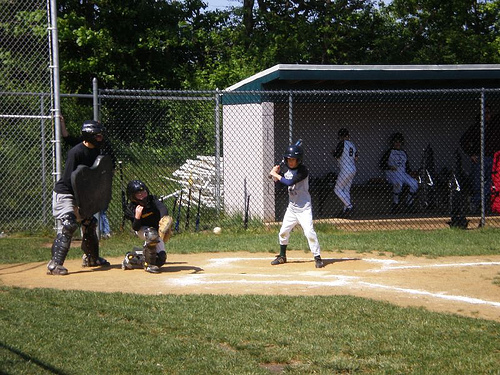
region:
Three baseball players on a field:
[41, 112, 338, 295]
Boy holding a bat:
[258, 129, 332, 283]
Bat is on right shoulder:
[264, 131, 308, 183]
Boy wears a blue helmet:
[265, 130, 333, 281]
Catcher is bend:
[111, 163, 183, 285]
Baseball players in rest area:
[327, 118, 458, 213]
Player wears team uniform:
[312, 118, 363, 213]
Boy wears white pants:
[257, 130, 335, 276]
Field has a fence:
[0, 3, 496, 239]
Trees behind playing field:
[31, 3, 496, 70]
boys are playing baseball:
[34, 108, 499, 294]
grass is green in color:
[103, 294, 234, 354]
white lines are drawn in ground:
[209, 231, 434, 371]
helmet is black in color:
[283, 145, 299, 163]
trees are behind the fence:
[20, 33, 255, 157]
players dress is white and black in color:
[256, 147, 331, 246]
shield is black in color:
[58, 156, 128, 218]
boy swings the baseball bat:
[248, 128, 333, 238]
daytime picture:
[48, 46, 481, 342]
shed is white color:
[218, 53, 456, 227]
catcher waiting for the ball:
[116, 172, 191, 274]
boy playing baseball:
[263, 129, 326, 275]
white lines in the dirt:
[163, 242, 498, 309]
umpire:
[43, 113, 119, 277]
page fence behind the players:
[0, 4, 66, 242]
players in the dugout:
[327, 122, 422, 221]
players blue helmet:
[282, 147, 309, 164]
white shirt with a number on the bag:
[333, 134, 363, 170]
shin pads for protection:
[42, 217, 112, 279]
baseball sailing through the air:
[203, 218, 229, 239]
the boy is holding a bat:
[265, 125, 341, 287]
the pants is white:
[273, 208, 325, 264]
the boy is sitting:
[379, 126, 442, 226]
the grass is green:
[21, 305, 258, 373]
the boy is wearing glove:
[124, 188, 194, 269]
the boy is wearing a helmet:
[74, 114, 122, 166]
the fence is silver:
[184, 88, 269, 173]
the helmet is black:
[282, 147, 306, 176]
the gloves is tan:
[155, 212, 182, 243]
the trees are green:
[139, 30, 259, 76]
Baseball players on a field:
[40, 110, 335, 291]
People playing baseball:
[34, 101, 347, 289]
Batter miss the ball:
[256, 127, 331, 274]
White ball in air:
[205, 215, 225, 237]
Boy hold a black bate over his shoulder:
[255, 115, 335, 281]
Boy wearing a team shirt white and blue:
[255, 123, 331, 294]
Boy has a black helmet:
[261, 127, 341, 272]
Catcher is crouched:
[118, 175, 183, 283]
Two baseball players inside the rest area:
[320, 115, 426, 215]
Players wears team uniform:
[317, 119, 430, 224]